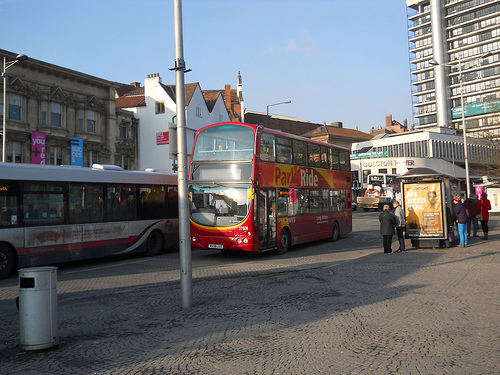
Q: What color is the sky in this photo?
A: Blue.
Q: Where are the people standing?
A: Bus stop.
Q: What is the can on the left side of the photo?
A: Trash can.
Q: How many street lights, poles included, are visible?
A: Four.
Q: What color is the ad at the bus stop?
A: Gold.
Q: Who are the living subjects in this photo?
A: Humans.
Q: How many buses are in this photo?
A: Two.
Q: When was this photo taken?
A: During the day.